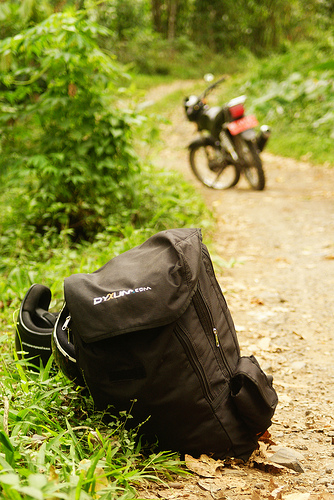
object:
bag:
[14, 227, 278, 463]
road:
[252, 198, 300, 229]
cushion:
[22, 283, 57, 333]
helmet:
[15, 283, 58, 373]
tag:
[213, 327, 220, 348]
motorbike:
[182, 73, 271, 191]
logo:
[93, 286, 151, 307]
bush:
[0, 0, 134, 235]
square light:
[229, 103, 244, 119]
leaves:
[32, 20, 76, 89]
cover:
[63, 227, 203, 345]